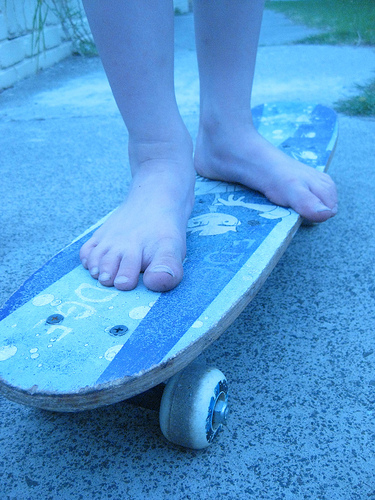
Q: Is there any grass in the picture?
A: Yes, there is grass.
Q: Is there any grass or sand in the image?
A: Yes, there is grass.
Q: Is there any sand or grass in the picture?
A: Yes, there is grass.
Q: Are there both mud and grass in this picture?
A: No, there is grass but no mud.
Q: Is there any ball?
A: No, there are no balls.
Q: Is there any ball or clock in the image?
A: No, there are no balls or clocks.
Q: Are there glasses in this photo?
A: No, there are no glasses.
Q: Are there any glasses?
A: No, there are no glasses.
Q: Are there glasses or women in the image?
A: No, there are no glasses or women.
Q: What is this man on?
A: The man is on the skateboard.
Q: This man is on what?
A: The man is on the skateboard.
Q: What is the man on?
A: The man is on the skateboard.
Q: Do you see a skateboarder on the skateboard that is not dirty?
A: No, there is a man on the skateboard.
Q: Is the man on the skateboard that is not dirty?
A: Yes, the man is on the skateboard.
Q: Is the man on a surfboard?
A: No, the man is on the skateboard.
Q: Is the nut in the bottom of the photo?
A: Yes, the nut is in the bottom of the image.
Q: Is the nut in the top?
A: No, the nut is in the bottom of the image.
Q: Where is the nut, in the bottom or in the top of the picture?
A: The nut is in the bottom of the image.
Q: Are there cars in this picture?
A: No, there are no cars.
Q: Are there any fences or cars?
A: No, there are no cars or fences.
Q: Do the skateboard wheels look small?
A: Yes, the wheels are small.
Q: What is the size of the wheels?
A: The wheels are small.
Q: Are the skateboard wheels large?
A: No, the wheels are small.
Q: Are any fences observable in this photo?
A: No, there are no fences.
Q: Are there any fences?
A: No, there are no fences.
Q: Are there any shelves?
A: No, there are no shelves.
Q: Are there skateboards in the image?
A: Yes, there is a skateboard.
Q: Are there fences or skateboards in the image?
A: Yes, there is a skateboard.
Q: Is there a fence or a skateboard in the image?
A: Yes, there is a skateboard.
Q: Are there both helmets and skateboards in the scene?
A: No, there is a skateboard but no helmets.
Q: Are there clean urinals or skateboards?
A: Yes, there is a clean skateboard.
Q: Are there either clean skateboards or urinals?
A: Yes, there is a clean skateboard.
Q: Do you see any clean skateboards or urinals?
A: Yes, there is a clean skateboard.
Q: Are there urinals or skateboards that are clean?
A: Yes, the skateboard is clean.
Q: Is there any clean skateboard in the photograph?
A: Yes, there is a clean skateboard.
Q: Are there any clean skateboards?
A: Yes, there is a clean skateboard.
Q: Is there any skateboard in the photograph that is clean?
A: Yes, there is a skateboard that is clean.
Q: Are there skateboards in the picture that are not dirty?
A: Yes, there is a clean skateboard.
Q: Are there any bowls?
A: No, there are no bowls.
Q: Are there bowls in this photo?
A: No, there are no bowls.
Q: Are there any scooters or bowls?
A: No, there are no bowls or scooters.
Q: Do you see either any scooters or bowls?
A: No, there are no bowls or scooters.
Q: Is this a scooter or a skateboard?
A: This is a skateboard.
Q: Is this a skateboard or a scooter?
A: This is a skateboard.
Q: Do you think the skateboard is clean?
A: Yes, the skateboard is clean.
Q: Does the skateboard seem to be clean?
A: Yes, the skateboard is clean.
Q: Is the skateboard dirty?
A: No, the skateboard is clean.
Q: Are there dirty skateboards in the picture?
A: No, there is a skateboard but it is clean.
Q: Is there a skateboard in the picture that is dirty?
A: No, there is a skateboard but it is clean.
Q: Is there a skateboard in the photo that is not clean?
A: No, there is a skateboard but it is clean.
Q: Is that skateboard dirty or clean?
A: The skateboard is clean.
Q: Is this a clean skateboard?
A: Yes, this is a clean skateboard.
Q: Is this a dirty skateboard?
A: No, this is a clean skateboard.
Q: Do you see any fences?
A: No, there are no fences.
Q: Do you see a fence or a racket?
A: No, there are no fences or rackets.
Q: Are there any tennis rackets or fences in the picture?
A: No, there are no fences or tennis rackets.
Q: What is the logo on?
A: The logo is on the skateboard.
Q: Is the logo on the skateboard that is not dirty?
A: Yes, the logo is on the skateboard.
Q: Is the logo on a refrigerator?
A: No, the logo is on the skateboard.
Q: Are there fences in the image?
A: No, there are no fences.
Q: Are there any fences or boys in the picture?
A: No, there are no fences or boys.